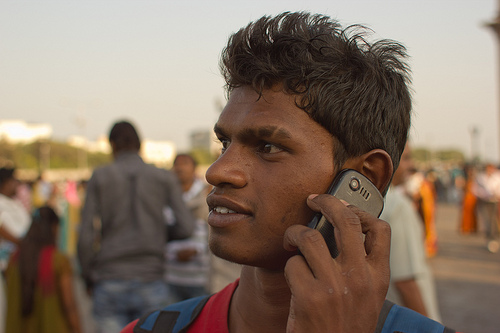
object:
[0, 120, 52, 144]
building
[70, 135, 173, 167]
building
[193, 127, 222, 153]
building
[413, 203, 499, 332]
ground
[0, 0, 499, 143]
sky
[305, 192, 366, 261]
fingers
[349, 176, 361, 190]
button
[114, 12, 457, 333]
man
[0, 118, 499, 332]
background people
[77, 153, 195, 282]
grey shirt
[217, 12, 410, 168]
hair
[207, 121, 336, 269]
face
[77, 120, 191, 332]
man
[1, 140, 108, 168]
tree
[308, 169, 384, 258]
cellphone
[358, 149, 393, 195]
ear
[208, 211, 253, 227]
lips